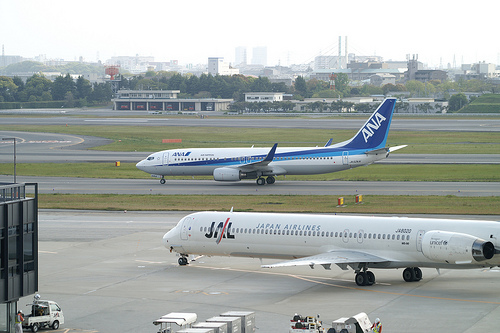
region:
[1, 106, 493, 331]
an image of a tarmac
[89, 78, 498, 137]
a terminal in the distance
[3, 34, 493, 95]
a downtown area in the background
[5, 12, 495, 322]
a scene outside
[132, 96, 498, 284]
a couple of planes on the runway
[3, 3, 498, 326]
a scene during the day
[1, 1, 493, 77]
a sky that is white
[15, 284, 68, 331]
a luggage cart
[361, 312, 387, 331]
a worker at the airport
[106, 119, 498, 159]
a green field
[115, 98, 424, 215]
A plane on a runway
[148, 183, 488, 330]
A long white plane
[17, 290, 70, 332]
A truck on a runway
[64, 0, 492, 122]
Buildings in the background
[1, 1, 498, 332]
Two planes on a runway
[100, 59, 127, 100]
A tall sign in the background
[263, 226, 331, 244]
Windows on a plane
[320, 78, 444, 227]
Tail wing on a plane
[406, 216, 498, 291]
Engine on a plane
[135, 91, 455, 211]
Blue on a plane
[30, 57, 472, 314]
photograph taken at sirport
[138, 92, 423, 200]
blue and white plane on runway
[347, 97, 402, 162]
blue tail of plane with letters in white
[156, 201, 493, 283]
white passenger plane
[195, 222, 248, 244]
company logo on plane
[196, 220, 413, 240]
long row of passenger windows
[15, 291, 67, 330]
trucks used to unload planes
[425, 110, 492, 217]
green grass in between runways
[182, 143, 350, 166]
two shades of a blue stripe on side of plane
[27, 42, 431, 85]
city in the background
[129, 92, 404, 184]
Large ANA passenger airplane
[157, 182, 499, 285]
JAL passenger airplane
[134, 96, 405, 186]
Passenger blue airplane ready for take-off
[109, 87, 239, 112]
Airport hangars with black doors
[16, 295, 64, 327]
Luggage loading truck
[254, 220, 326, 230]
Japan Airlines writing on plane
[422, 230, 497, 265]
Large airplane engine with black front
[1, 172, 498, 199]
Runway for passenger airplanes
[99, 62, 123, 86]
Red airport radio tower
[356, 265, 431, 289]
Rear wheels on passenger airplane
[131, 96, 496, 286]
two planes on a tarmac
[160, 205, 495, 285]
a white plane on the tarmac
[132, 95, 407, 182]
a blue and white airplane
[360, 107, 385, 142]
letters on the tail of the blue and white plane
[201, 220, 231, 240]
bold black letters on the white plane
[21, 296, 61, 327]
small white truck in lower left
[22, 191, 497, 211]
patch of grass between the two planes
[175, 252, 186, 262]
front landing wheel on the white plane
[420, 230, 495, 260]
the engine on the white plane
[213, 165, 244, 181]
engine on the blue and white plane